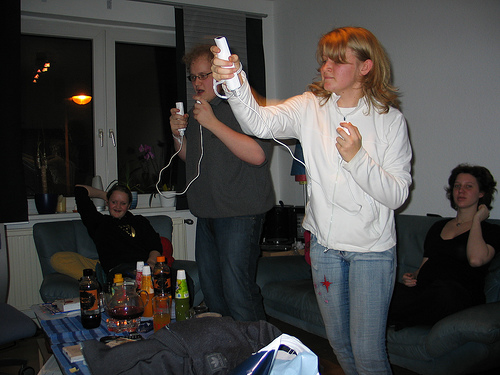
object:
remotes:
[210, 33, 238, 92]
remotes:
[170, 98, 189, 137]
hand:
[312, 110, 387, 167]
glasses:
[310, 50, 376, 68]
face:
[316, 47, 355, 92]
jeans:
[312, 240, 406, 371]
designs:
[311, 270, 336, 305]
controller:
[200, 31, 246, 96]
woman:
[377, 157, 499, 325]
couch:
[179, 185, 498, 375]